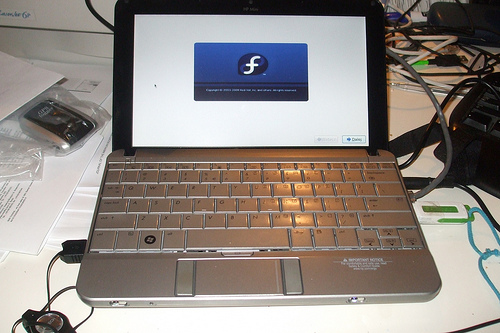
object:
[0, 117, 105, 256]
papers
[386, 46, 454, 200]
wires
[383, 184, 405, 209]
ground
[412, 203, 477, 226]
flash drive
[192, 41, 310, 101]
logo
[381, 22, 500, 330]
table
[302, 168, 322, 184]
keys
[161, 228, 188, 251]
keys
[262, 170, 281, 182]
keys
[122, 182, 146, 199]
keys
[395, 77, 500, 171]
wires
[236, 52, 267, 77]
logo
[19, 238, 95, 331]
something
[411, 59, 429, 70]
marker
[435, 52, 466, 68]
usb cable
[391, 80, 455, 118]
ground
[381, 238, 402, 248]
arrow keys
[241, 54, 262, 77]
'f'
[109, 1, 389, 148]
screen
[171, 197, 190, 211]
key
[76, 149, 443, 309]
keyboard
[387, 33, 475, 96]
wires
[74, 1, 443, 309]
laptop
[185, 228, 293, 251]
space bar